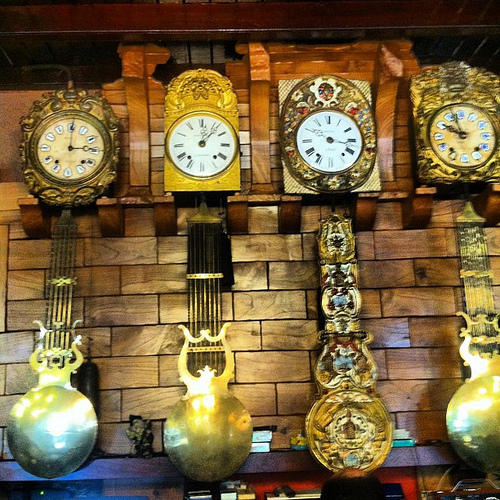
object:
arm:
[203, 129, 215, 139]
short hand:
[333, 137, 347, 147]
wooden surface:
[381, 235, 453, 387]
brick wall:
[238, 242, 305, 331]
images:
[322, 400, 387, 462]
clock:
[156, 64, 258, 487]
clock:
[6, 79, 123, 477]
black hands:
[66, 139, 103, 154]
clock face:
[19, 85, 123, 206]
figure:
[125, 412, 161, 461]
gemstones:
[309, 80, 343, 111]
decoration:
[317, 275, 370, 327]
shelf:
[66, 429, 476, 500]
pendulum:
[3, 214, 103, 478]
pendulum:
[163, 197, 259, 483]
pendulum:
[303, 203, 395, 475]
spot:
[185, 370, 218, 416]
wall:
[3, 2, 500, 483]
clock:
[160, 65, 247, 196]